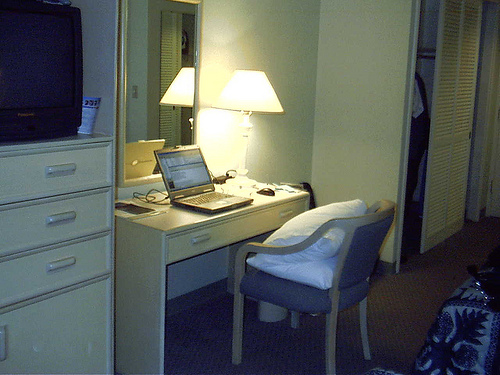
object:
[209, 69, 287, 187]
lamp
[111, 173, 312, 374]
desk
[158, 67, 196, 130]
lampshade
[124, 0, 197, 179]
mirror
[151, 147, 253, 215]
laptop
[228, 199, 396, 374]
chair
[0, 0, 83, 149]
tv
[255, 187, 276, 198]
mouse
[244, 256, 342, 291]
pillow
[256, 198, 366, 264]
pillow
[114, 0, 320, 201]
wall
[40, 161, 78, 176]
drawer handle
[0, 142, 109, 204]
drawer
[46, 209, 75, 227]
drawer handle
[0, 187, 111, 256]
drawer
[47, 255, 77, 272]
drawer handle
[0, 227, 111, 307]
drawer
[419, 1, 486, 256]
closet door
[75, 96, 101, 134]
paper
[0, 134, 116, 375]
dresser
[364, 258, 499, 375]
blanket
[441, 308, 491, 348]
designs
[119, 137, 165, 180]
laptop reflection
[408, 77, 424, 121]
clothes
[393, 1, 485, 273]
closet